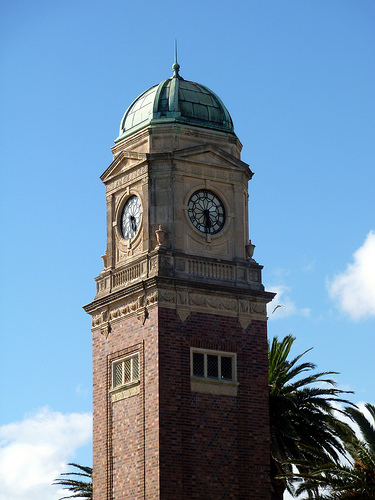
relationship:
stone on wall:
[173, 220, 184, 237] [155, 140, 272, 498]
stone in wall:
[152, 177, 171, 192] [94, 123, 264, 301]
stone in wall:
[153, 187, 170, 206] [94, 123, 264, 301]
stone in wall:
[172, 234, 187, 250] [94, 123, 264, 301]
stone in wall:
[151, 135, 172, 152] [94, 123, 264, 301]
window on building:
[188, 344, 206, 380] [80, 273, 277, 499]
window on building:
[189, 348, 205, 380] [92, 72, 268, 498]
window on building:
[189, 348, 238, 383] [51, 34, 301, 359]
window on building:
[206, 352, 220, 381] [83, 40, 275, 499]